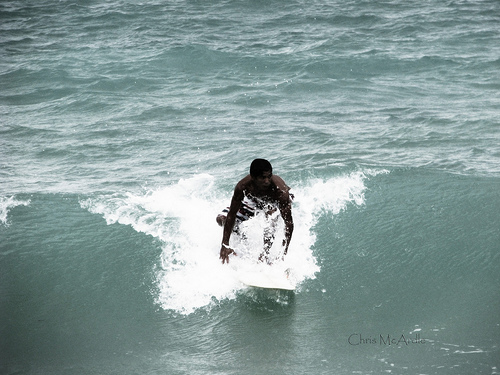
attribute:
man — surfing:
[217, 157, 296, 263]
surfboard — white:
[228, 243, 291, 290]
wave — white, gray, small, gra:
[0, 169, 494, 298]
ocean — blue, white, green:
[1, 1, 499, 374]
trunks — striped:
[222, 194, 294, 234]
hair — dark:
[251, 159, 269, 176]